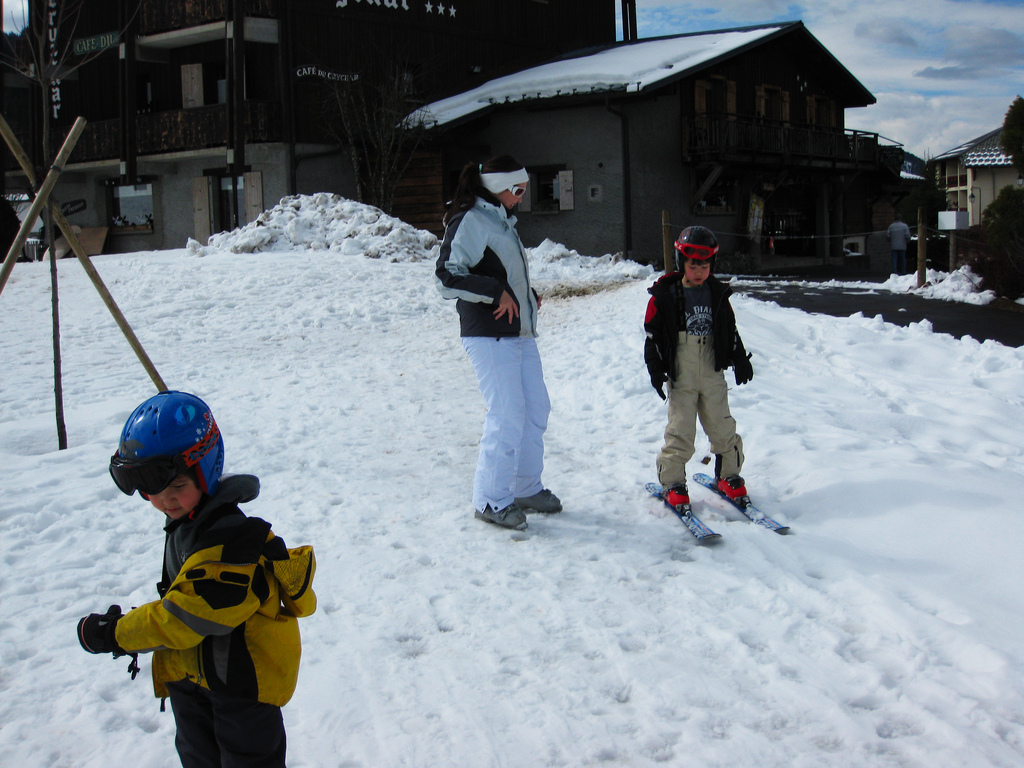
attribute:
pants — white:
[450, 326, 568, 524]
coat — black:
[432, 196, 540, 337]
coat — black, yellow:
[109, 506, 321, 716]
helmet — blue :
[105, 386, 224, 504]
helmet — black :
[664, 223, 725, 287]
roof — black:
[390, 17, 877, 125]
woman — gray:
[425, 144, 566, 533]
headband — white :
[475, 165, 534, 197]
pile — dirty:
[177, 187, 435, 261]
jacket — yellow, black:
[108, 471, 321, 722]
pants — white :
[456, 336, 552, 510]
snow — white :
[2, 20, 1021, 766]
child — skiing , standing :
[637, 219, 764, 507]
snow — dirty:
[269, 144, 341, 281]